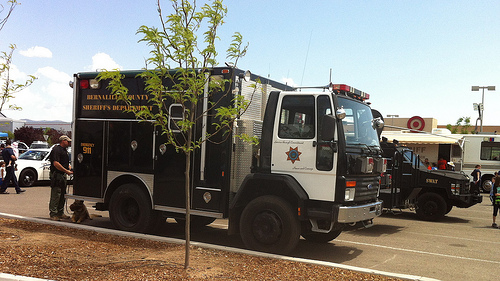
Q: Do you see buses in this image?
A: No, there are no buses.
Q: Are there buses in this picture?
A: No, there are no buses.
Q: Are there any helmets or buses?
A: No, there are no buses or helmets.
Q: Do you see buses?
A: No, there are no buses.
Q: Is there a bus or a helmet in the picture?
A: No, there are no buses or helmets.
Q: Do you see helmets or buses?
A: No, there are no buses or helmets.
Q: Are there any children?
A: Yes, there is a child.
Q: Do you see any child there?
A: Yes, there is a child.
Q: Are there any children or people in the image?
A: Yes, there is a child.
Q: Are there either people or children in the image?
A: Yes, there is a child.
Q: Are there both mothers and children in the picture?
A: No, there is a child but no mothers.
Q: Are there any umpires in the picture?
A: No, there are no umpires.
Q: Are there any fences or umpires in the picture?
A: No, there are no umpires or fences.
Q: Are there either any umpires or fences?
A: No, there are no umpires or fences.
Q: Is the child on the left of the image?
A: Yes, the child is on the left of the image.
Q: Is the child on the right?
A: No, the child is on the left of the image.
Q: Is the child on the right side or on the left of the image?
A: The child is on the left of the image.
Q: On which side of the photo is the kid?
A: The kid is on the left of the image.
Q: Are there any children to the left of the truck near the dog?
A: Yes, there is a child to the left of the truck.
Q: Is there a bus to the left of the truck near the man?
A: No, there is a child to the left of the truck.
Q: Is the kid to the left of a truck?
A: Yes, the kid is to the left of a truck.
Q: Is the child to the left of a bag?
A: No, the child is to the left of a truck.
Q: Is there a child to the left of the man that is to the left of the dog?
A: Yes, there is a child to the left of the man.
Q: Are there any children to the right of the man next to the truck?
A: No, the child is to the left of the man.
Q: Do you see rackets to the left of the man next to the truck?
A: No, there is a child to the left of the man.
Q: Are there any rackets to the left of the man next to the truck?
A: No, there is a child to the left of the man.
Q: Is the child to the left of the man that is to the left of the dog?
A: Yes, the child is to the left of the man.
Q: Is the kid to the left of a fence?
A: No, the kid is to the left of the man.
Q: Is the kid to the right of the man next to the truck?
A: No, the kid is to the left of the man.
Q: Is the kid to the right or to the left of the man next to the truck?
A: The kid is to the left of the man.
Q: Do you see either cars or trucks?
A: Yes, there is a truck.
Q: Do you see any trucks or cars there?
A: Yes, there is a truck.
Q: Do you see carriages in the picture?
A: No, there are no carriages.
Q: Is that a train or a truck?
A: That is a truck.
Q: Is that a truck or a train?
A: That is a truck.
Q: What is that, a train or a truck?
A: That is a truck.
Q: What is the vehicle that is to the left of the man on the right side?
A: The vehicle is a truck.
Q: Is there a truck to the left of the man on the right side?
A: Yes, there is a truck to the left of the man.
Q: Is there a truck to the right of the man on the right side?
A: No, the truck is to the left of the man.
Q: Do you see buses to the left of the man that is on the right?
A: No, there is a truck to the left of the man.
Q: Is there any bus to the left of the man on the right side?
A: No, there is a truck to the left of the man.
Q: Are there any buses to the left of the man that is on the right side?
A: No, there is a truck to the left of the man.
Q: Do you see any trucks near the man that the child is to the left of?
A: Yes, there is a truck near the man.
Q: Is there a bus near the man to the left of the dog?
A: No, there is a truck near the man.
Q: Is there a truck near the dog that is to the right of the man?
A: Yes, there is a truck near the dog.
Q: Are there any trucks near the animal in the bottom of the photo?
A: Yes, there is a truck near the dog.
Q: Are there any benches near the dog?
A: No, there is a truck near the dog.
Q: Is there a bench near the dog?
A: No, there is a truck near the dog.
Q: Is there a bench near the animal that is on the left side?
A: No, there is a truck near the dog.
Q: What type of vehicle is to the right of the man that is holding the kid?
A: The vehicle is a truck.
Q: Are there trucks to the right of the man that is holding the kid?
A: Yes, there is a truck to the right of the man.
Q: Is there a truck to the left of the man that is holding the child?
A: No, the truck is to the right of the man.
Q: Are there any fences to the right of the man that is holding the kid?
A: No, there is a truck to the right of the man.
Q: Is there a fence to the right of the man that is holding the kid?
A: No, there is a truck to the right of the man.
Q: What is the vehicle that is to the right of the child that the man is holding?
A: The vehicle is a truck.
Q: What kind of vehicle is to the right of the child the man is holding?
A: The vehicle is a truck.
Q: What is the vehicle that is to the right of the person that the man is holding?
A: The vehicle is a truck.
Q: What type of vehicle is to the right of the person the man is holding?
A: The vehicle is a truck.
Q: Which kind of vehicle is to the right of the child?
A: The vehicle is a truck.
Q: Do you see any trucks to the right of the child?
A: Yes, there is a truck to the right of the child.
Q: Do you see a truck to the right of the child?
A: Yes, there is a truck to the right of the child.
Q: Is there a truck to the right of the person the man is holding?
A: Yes, there is a truck to the right of the child.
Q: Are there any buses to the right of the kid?
A: No, there is a truck to the right of the kid.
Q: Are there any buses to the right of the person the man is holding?
A: No, there is a truck to the right of the kid.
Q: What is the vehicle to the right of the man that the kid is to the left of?
A: The vehicle is a truck.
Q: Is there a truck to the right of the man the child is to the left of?
A: Yes, there is a truck to the right of the man.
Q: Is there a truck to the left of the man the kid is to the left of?
A: No, the truck is to the right of the man.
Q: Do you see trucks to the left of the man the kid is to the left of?
A: No, the truck is to the right of the man.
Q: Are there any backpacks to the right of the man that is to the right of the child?
A: No, there is a truck to the right of the man.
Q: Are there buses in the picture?
A: No, there are no buses.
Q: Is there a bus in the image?
A: No, there are no buses.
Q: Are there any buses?
A: No, there are no buses.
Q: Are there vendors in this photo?
A: No, there are no vendors.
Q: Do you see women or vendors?
A: No, there are no vendors or women.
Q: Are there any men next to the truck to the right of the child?
A: Yes, there is a man next to the truck.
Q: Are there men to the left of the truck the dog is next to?
A: Yes, there is a man to the left of the truck.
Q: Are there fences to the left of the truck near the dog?
A: No, there is a man to the left of the truck.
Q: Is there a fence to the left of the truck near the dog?
A: No, there is a man to the left of the truck.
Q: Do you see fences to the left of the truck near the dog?
A: No, there is a man to the left of the truck.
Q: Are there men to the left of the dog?
A: Yes, there is a man to the left of the dog.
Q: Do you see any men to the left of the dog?
A: Yes, there is a man to the left of the dog.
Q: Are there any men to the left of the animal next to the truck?
A: Yes, there is a man to the left of the dog.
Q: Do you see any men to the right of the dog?
A: No, the man is to the left of the dog.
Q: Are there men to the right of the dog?
A: No, the man is to the left of the dog.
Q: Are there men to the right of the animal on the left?
A: No, the man is to the left of the dog.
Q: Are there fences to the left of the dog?
A: No, there is a man to the left of the dog.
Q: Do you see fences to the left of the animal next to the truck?
A: No, there is a man to the left of the dog.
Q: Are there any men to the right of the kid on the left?
A: Yes, there is a man to the right of the kid.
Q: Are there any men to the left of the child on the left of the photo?
A: No, the man is to the right of the kid.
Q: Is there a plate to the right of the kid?
A: No, there is a man to the right of the kid.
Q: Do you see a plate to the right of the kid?
A: No, there is a man to the right of the kid.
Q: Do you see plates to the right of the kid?
A: No, there is a man to the right of the kid.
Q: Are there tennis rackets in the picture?
A: No, there are no tennis rackets.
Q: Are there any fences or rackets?
A: No, there are no rackets or fences.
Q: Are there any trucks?
A: Yes, there is a truck.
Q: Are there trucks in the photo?
A: Yes, there is a truck.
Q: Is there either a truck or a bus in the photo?
A: Yes, there is a truck.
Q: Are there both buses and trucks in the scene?
A: No, there is a truck but no buses.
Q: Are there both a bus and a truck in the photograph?
A: No, there is a truck but no buses.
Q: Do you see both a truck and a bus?
A: No, there is a truck but no buses.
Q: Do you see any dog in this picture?
A: Yes, there is a dog.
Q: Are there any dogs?
A: Yes, there is a dog.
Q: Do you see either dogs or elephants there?
A: Yes, there is a dog.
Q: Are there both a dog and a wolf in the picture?
A: No, there is a dog but no wolves.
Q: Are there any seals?
A: No, there are no seals.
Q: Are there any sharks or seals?
A: No, there are no seals or sharks.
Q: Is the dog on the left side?
A: Yes, the dog is on the left of the image.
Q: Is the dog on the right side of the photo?
A: No, the dog is on the left of the image.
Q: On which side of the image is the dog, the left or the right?
A: The dog is on the left of the image.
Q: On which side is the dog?
A: The dog is on the left of the image.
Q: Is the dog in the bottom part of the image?
A: Yes, the dog is in the bottom of the image.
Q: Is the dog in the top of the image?
A: No, the dog is in the bottom of the image.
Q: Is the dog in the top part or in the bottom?
A: The dog is in the bottom of the image.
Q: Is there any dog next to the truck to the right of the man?
A: Yes, there is a dog next to the truck.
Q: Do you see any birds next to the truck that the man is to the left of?
A: No, there is a dog next to the truck.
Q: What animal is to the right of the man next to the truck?
A: The animal is a dog.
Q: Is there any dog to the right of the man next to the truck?
A: Yes, there is a dog to the right of the man.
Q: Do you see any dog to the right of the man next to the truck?
A: Yes, there is a dog to the right of the man.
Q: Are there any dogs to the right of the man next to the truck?
A: Yes, there is a dog to the right of the man.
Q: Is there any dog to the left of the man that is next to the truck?
A: No, the dog is to the right of the man.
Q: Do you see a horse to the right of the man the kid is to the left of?
A: No, there is a dog to the right of the man.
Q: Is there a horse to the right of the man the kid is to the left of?
A: No, there is a dog to the right of the man.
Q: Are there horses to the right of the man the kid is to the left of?
A: No, there is a dog to the right of the man.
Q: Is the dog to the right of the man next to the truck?
A: Yes, the dog is to the right of the man.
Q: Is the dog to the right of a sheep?
A: No, the dog is to the right of the man.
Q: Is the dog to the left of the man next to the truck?
A: No, the dog is to the right of the man.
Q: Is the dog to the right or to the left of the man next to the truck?
A: The dog is to the right of the man.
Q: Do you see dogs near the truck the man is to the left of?
A: Yes, there is a dog near the truck.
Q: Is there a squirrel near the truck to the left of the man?
A: No, there is a dog near the truck.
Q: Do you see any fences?
A: No, there are no fences.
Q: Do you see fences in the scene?
A: No, there are no fences.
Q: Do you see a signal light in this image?
A: No, there are no traffic lights.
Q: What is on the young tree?
A: The leaves are on the tree.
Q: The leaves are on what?
A: The leaves are on the tree.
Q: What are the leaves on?
A: The leaves are on the tree.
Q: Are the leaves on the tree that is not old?
A: Yes, the leaves are on the tree.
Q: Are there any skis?
A: No, there are no skis.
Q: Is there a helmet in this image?
A: No, there are no helmets.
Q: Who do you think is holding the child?
A: The man is holding the child.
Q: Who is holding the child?
A: The man is holding the child.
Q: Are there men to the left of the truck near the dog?
A: Yes, there is a man to the left of the truck.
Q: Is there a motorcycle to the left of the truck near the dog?
A: No, there is a man to the left of the truck.